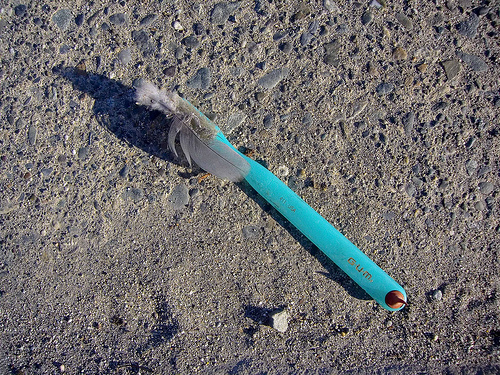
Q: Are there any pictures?
A: No, there are no pictures.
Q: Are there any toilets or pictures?
A: No, there are no pictures or toilets.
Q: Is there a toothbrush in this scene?
A: Yes, there is a toothbrush.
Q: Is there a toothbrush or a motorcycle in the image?
A: Yes, there is a toothbrush.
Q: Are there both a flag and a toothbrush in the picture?
A: No, there is a toothbrush but no flags.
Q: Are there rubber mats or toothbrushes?
A: Yes, there is a rubber toothbrush.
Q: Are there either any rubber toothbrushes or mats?
A: Yes, there is a rubber toothbrush.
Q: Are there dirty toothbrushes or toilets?
A: Yes, there is a dirty toothbrush.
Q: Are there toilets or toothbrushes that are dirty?
A: Yes, the toothbrush is dirty.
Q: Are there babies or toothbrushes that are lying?
A: Yes, the toothbrush is lying.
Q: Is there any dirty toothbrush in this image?
A: Yes, there is a dirty toothbrush.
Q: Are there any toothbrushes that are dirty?
A: Yes, there is a toothbrush that is dirty.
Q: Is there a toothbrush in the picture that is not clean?
A: Yes, there is a dirty toothbrush.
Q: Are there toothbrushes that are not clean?
A: Yes, there is a dirty toothbrush.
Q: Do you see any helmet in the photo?
A: No, there are no helmets.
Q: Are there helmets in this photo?
A: No, there are no helmets.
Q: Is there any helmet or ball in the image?
A: No, there are no helmets or balls.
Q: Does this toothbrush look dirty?
A: Yes, the toothbrush is dirty.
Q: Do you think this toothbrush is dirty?
A: Yes, the toothbrush is dirty.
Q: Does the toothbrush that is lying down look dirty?
A: Yes, the toothbrush is dirty.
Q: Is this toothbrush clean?
A: No, the toothbrush is dirty.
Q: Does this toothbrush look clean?
A: No, the toothbrush is dirty.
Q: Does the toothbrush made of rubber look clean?
A: No, the toothbrush is dirty.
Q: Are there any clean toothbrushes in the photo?
A: No, there is a toothbrush but it is dirty.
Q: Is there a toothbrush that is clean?
A: No, there is a toothbrush but it is dirty.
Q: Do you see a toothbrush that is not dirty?
A: No, there is a toothbrush but it is dirty.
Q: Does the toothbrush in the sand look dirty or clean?
A: The toothbrush is dirty.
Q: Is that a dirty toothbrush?
A: Yes, that is a dirty toothbrush.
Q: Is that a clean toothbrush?
A: No, that is a dirty toothbrush.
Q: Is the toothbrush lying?
A: Yes, the toothbrush is lying.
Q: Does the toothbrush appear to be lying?
A: Yes, the toothbrush is lying.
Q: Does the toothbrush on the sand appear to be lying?
A: Yes, the toothbrush is lying.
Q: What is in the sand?
A: The toothbrush is in the sand.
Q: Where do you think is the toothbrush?
A: The toothbrush is in the sand.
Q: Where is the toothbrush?
A: The toothbrush is in the sand.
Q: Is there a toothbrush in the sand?
A: Yes, there is a toothbrush in the sand.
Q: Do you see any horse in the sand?
A: No, there is a toothbrush in the sand.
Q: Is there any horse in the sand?
A: No, there is a toothbrush in the sand.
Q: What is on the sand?
A: The toothbrush is on the sand.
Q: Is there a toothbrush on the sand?
A: Yes, there is a toothbrush on the sand.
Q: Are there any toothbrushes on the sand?
A: Yes, there is a toothbrush on the sand.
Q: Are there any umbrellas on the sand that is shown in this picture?
A: No, there is a toothbrush on the sand.